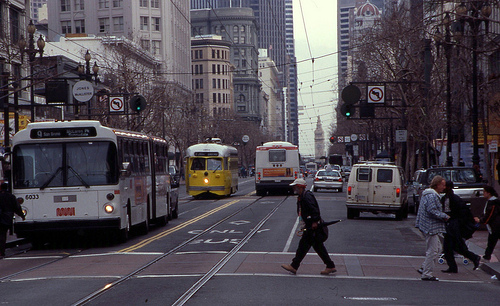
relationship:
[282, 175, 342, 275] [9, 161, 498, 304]
man crossing street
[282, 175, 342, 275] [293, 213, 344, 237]
man carrying umbrella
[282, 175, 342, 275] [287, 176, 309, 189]
man wearing hat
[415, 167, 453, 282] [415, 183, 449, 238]
man in shirt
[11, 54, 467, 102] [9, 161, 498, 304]
power line over street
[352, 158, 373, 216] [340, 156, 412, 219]
ladder on van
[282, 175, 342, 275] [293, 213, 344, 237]
man with umbrella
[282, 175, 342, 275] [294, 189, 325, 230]
man wearing jacket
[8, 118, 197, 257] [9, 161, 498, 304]
bus on street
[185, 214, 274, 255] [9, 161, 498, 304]
words in street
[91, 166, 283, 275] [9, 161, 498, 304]
line on street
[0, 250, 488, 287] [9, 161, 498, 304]
crosswalk on street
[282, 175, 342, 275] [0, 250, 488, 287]
man in crosswalk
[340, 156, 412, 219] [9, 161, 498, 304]
van in street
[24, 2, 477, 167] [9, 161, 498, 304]
power line above road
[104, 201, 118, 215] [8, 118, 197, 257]
light on bus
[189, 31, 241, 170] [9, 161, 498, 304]
building on street